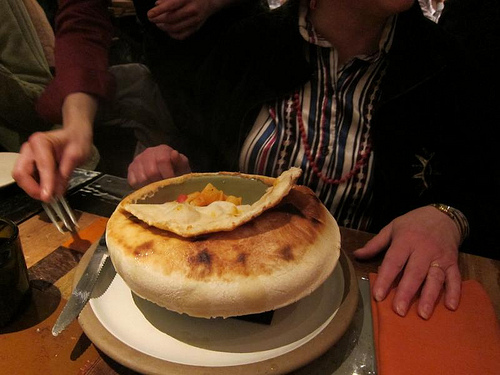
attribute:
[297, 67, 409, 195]
necklace — red, pearl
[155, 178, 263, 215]
peaches — pieces, baked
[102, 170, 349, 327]
pie — giant, peach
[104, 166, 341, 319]
pot pie — large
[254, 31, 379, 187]
necklace — red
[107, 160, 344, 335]
pie — giant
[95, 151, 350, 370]
meal — cooked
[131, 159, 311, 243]
crust — piece, pulled to the side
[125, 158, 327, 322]
pot pie — cooked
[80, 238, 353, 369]
plate — white, brown